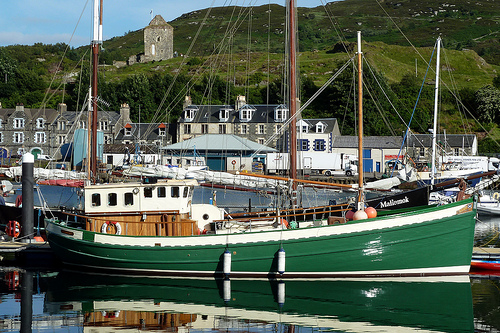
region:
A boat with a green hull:
[46, 207, 477, 332]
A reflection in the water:
[44, 291, 275, 331]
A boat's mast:
[356, 26, 366, 206]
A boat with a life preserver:
[99, 217, 121, 235]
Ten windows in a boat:
[90, 185, 195, 207]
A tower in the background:
[143, 15, 173, 60]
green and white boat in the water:
[47, 18, 472, 280]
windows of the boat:
[90, 181, 195, 206]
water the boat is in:
[4, 257, 499, 332]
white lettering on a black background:
[377, 195, 409, 209]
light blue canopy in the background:
[156, 132, 271, 173]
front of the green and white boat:
[365, 196, 470, 292]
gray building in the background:
[1, 106, 77, 161]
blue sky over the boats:
[1, 0, 331, 50]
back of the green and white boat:
[44, 179, 126, 261]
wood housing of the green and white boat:
[83, 210, 198, 237]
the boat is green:
[43, 178, 488, 312]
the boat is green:
[49, 171, 484, 313]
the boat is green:
[44, 163, 481, 321]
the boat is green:
[47, 162, 486, 305]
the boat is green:
[44, 165, 491, 315]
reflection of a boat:
[52, 282, 303, 330]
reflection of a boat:
[69, 285, 181, 325]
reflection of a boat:
[74, 280, 217, 325]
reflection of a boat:
[72, 285, 277, 328]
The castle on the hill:
[145, 13, 183, 62]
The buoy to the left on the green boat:
[218, 245, 239, 276]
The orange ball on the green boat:
[364, 201, 377, 217]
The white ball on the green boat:
[352, 208, 368, 225]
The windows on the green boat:
[81, 186, 148, 214]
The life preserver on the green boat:
[97, 215, 124, 239]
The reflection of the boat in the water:
[33, 296, 332, 331]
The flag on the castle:
[146, 8, 156, 21]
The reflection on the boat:
[361, 235, 394, 259]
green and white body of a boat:
[42, 194, 474, 274]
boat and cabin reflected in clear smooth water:
[3, 281, 426, 332]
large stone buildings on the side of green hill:
[105, 12, 180, 67]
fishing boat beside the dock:
[41, 178, 476, 289]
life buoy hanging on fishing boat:
[97, 219, 122, 239]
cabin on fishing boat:
[82, 181, 192, 214]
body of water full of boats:
[0, 173, 498, 331]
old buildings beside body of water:
[0, 93, 481, 159]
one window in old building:
[182, 125, 191, 135]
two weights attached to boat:
[222, 248, 287, 276]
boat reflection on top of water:
[62, 287, 497, 331]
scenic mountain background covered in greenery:
[0, 0, 498, 159]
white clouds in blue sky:
[1, 29, 86, 45]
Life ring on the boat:
[99, 218, 124, 235]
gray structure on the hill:
[135, 10, 179, 65]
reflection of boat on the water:
[75, 295, 212, 332]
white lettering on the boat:
[374, 190, 409, 207]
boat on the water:
[41, 172, 498, 286]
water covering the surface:
[0, 265, 495, 330]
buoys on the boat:
[349, 200, 376, 222]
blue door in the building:
[372, 158, 383, 173]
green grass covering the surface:
[0, 0, 496, 136]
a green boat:
[23, 178, 488, 293]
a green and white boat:
[28, 183, 481, 285]